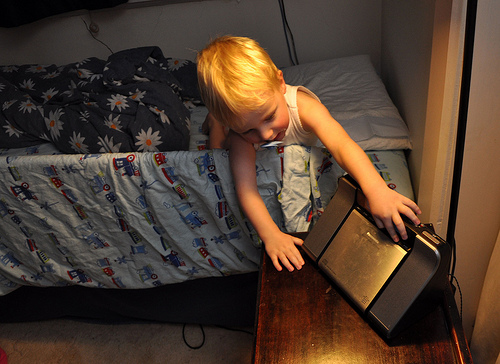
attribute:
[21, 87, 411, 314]
blanket — white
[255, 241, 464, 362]
table — brown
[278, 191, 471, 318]
radio — black, silver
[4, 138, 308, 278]
blanket — white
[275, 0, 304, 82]
cable wire — black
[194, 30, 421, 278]
toddler — blond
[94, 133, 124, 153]
flowers — white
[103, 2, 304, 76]
pillow — white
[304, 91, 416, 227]
arm — extended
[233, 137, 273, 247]
arm — extended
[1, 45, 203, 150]
blanket — white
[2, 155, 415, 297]
sheet — train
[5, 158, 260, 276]
blanket — white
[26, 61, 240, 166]
blanket — gray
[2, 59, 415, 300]
blanket — white